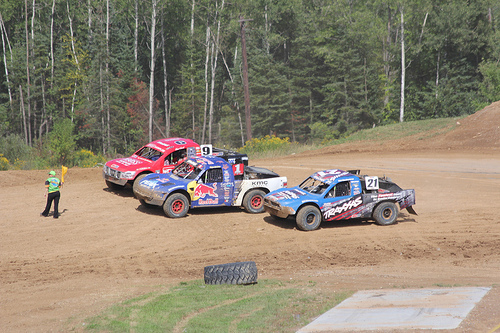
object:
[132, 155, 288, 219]
cars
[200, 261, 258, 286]
tire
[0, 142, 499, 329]
race track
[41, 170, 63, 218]
man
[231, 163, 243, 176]
1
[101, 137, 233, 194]
car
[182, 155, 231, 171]
top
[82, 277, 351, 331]
green grass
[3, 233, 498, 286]
track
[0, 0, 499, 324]
background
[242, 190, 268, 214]
wheel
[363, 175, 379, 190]
number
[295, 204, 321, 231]
front wheel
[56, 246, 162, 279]
lines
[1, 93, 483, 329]
dirt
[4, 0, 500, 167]
trees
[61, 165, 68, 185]
flag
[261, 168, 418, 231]
car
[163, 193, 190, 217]
rims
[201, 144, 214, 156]
numbers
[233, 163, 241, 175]
number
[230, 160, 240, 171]
background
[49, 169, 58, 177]
cap